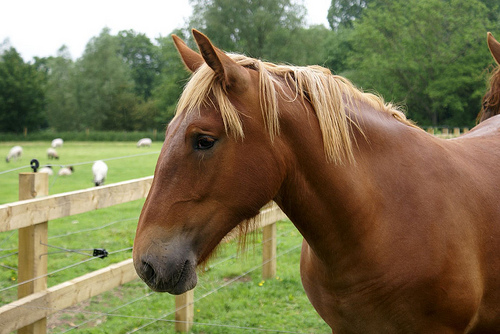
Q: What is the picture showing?
A: It is showing a field.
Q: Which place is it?
A: It is a field.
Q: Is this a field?
A: Yes, it is a field.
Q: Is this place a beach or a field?
A: It is a field.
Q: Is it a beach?
A: No, it is a field.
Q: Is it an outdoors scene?
A: Yes, it is outdoors.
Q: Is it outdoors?
A: Yes, it is outdoors.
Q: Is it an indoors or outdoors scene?
A: It is outdoors.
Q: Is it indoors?
A: No, it is outdoors.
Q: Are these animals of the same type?
A: No, there are both sheep and horses.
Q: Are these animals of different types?
A: Yes, they are sheep and horses.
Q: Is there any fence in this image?
A: Yes, there is a fence.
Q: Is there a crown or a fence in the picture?
A: Yes, there is a fence.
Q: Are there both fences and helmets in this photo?
A: No, there is a fence but no helmets.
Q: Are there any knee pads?
A: No, there are no knee pads.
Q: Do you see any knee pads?
A: No, there are no knee pads.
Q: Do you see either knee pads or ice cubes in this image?
A: No, there are no knee pads or ice cubes.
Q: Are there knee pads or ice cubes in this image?
A: No, there are no knee pads or ice cubes.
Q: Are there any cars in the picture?
A: No, there are no cars.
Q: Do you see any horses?
A: Yes, there is a horse.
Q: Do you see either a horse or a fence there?
A: Yes, there is a horse.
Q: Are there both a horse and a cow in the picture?
A: No, there is a horse but no cows.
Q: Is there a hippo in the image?
A: No, there are no hippoes.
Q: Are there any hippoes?
A: No, there are no hippoes.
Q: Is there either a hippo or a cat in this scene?
A: No, there are no hippoes or cats.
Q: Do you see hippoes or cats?
A: No, there are no hippoes or cats.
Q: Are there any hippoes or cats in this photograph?
A: No, there are no hippoes or cats.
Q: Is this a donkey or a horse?
A: This is a horse.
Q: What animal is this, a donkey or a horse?
A: This is a horse.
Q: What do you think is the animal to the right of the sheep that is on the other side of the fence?
A: The animal is a horse.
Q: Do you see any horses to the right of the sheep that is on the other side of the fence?
A: Yes, there is a horse to the right of the sheep.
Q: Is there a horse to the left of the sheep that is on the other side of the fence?
A: No, the horse is to the right of the sheep.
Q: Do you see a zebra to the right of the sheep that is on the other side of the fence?
A: No, there is a horse to the right of the sheep.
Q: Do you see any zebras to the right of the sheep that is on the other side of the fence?
A: No, there is a horse to the right of the sheep.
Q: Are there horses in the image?
A: Yes, there is a horse.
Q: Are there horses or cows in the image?
A: Yes, there is a horse.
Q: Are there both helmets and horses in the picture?
A: No, there is a horse but no helmets.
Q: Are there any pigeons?
A: No, there are no pigeons.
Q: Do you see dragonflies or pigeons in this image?
A: No, there are no pigeons or dragonflies.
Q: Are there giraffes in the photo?
A: No, there are no giraffes.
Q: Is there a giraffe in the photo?
A: No, there are no giraffes.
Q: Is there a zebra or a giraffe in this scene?
A: No, there are no giraffes or zebras.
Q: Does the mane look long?
A: Yes, the mane is long.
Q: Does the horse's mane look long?
A: Yes, the mane is long.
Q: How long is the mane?
A: The mane is long.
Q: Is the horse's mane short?
A: No, the mane is long.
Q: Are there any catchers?
A: No, there are no catchers.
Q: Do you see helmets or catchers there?
A: No, there are no catchers or helmets.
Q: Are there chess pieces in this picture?
A: No, there are no chess pieces.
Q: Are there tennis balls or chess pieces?
A: No, there are no chess pieces or tennis balls.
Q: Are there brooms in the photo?
A: No, there are no brooms.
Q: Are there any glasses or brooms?
A: No, there are no brooms or glasses.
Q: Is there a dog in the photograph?
A: No, there are no dogs.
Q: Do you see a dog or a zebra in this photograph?
A: No, there are no dogs or zebras.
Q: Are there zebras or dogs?
A: No, there are no dogs or zebras.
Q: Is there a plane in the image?
A: No, there are no airplanes.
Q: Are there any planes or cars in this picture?
A: No, there are no planes or cars.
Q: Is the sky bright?
A: Yes, the sky is bright.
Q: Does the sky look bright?
A: Yes, the sky is bright.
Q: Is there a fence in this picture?
A: Yes, there is a fence.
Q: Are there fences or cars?
A: Yes, there is a fence.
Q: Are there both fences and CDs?
A: No, there is a fence but no cds.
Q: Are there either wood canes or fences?
A: Yes, there is a wood fence.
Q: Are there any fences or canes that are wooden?
A: Yes, the fence is wooden.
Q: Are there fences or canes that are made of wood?
A: Yes, the fence is made of wood.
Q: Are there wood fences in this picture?
A: Yes, there is a wood fence.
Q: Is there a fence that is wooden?
A: Yes, there is a fence that is wooden.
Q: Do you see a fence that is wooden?
A: Yes, there is a fence that is wooden.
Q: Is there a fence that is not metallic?
A: Yes, there is a wooden fence.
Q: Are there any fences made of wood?
A: Yes, there is a fence that is made of wood.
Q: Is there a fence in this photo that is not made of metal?
A: Yes, there is a fence that is made of wood.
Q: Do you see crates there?
A: No, there are no crates.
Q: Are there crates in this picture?
A: No, there are no crates.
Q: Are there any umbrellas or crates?
A: No, there are no crates or umbrellas.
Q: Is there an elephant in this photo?
A: No, there are no elephants.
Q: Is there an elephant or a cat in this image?
A: No, there are no elephants or cats.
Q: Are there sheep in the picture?
A: Yes, there is a sheep.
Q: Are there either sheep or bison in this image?
A: Yes, there is a sheep.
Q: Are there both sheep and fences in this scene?
A: Yes, there are both a sheep and a fence.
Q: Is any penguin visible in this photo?
A: No, there are no penguins.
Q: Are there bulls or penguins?
A: No, there are no penguins or bulls.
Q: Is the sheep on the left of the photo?
A: Yes, the sheep is on the left of the image.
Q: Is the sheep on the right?
A: No, the sheep is on the left of the image.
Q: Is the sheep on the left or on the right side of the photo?
A: The sheep is on the left of the image.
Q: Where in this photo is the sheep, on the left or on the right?
A: The sheep is on the left of the image.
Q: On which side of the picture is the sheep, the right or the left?
A: The sheep is on the left of the image.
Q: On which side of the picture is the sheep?
A: The sheep is on the left of the image.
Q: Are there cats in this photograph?
A: No, there are no cats.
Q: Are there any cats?
A: No, there are no cats.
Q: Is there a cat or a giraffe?
A: No, there are no cats or giraffes.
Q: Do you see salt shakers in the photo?
A: No, there are no salt shakers.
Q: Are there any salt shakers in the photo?
A: No, there are no salt shakers.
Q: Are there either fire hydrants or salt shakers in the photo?
A: No, there are no salt shakers or fire hydrants.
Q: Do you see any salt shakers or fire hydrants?
A: No, there are no salt shakers or fire hydrants.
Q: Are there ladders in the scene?
A: No, there are no ladders.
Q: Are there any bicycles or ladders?
A: No, there are no ladders or bicycles.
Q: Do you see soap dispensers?
A: No, there are no soap dispensers.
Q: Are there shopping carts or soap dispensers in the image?
A: No, there are no soap dispensers or shopping carts.